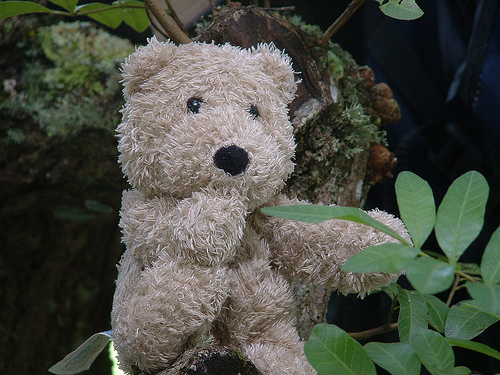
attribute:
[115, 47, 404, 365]
bear — brown, fuzzy, light, plush, worse, beige, shaggy, cream, stuffed, tan, lonely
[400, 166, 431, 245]
leaf — green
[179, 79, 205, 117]
eye — black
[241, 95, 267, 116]
eye — black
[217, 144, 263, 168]
nose — black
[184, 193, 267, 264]
paw — up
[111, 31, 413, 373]
toy — brown, plush, favorite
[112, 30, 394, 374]
animal — stuffed, plush, brown, light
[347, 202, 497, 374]
plant — green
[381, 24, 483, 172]
pattern — flowers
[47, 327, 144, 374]
tag — attached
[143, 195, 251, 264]
arm — out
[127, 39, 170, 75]
ear — small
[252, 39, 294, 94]
ear — small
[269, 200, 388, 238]
leaf — green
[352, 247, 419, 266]
leaf — green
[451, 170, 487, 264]
leaf — green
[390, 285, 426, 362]
leaf — green